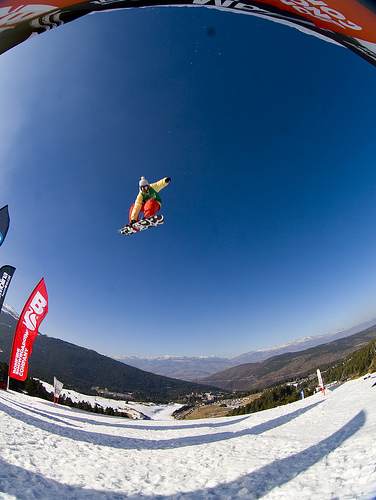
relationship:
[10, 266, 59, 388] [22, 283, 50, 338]
flag has letters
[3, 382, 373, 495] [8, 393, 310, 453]
snow has shadows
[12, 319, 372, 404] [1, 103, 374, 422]
mountains in distance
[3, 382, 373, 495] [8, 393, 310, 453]
snow with shadows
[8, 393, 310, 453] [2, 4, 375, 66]
shadows from flags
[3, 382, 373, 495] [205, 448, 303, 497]
snow has footprints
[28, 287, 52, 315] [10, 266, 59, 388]
b against red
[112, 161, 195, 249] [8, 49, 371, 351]
snowboarder in air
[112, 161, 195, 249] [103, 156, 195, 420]
snowboarder performing trick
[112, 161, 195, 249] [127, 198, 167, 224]
snowboarder wearing pants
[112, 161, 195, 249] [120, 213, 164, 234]
snowboarder gripping snowboard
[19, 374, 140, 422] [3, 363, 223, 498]
trees on path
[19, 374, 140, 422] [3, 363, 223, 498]
trees along path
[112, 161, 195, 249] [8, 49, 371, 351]
snowboarder floating in air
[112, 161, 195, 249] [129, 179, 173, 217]
snowboarder wearing outfit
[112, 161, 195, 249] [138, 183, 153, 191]
snowboarder wearing googles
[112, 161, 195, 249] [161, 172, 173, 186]
snowboarder wearing glove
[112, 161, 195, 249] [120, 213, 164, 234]
snowboarder on snowboard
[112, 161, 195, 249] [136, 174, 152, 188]
snowboarder wearing beanie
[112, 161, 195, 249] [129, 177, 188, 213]
snowboarder wearing jacket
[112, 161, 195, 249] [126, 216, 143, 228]
snowboarder has hand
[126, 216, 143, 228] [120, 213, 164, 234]
hand on top of snowboard